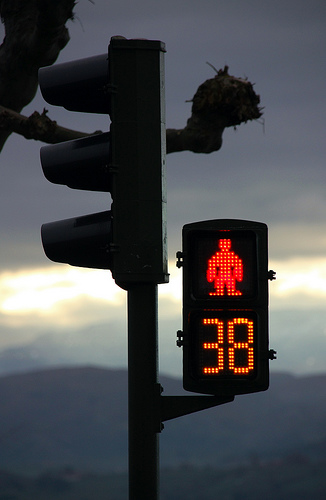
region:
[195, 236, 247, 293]
red man on light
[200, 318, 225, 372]
orange number on light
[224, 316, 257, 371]
orange number on light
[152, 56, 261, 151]
black protrusion behind light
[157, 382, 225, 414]
black protrusion on light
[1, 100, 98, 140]
black protrusion behind light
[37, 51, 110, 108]
black protrusion on light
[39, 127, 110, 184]
black protrusion on light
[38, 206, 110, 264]
black protrusion on light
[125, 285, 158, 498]
black pole of light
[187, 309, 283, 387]
light's in the shape of numbers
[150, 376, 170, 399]
bolt on a pole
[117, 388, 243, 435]
arm holding the lights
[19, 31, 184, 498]
pole with light's hanging on it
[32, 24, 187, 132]
top of the light pole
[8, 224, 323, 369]
horizon behind the light's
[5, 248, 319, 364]
cloud's in the sky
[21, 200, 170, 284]
bottom of the stop light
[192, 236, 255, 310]
light's shaped like a person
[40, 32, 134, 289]
light's on top of each other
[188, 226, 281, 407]
red signal light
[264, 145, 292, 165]
white clouds in blue sky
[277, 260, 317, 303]
white clouds in blue sky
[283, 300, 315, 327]
white clouds in blue sky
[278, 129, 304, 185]
white clouds in blue sky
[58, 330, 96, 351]
white clouds in blue sky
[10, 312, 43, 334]
white clouds in blue sky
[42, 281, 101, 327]
white clouds in blue sky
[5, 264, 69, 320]
white clouds in blue sky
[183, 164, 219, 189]
white clouds in blue sky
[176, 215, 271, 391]
number 38 and a symbol of a man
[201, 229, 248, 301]
red light symbol of a man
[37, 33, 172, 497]
side view of a traffic light pole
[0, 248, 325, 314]
sun shining through a cloudy sky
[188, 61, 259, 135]
a nest on a tree branch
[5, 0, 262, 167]
tree branch behind the traffic light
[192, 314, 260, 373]
the number 38 lit up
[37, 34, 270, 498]
traffic light post in focus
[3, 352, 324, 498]
out of focus blurry mountains in the distance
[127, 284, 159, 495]
pole holding up the traffic lights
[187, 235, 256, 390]
traffic light is on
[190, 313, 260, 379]
38 on the sign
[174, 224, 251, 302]
person on the sign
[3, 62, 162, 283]
side of traffic light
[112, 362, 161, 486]
pole for the lights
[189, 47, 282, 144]
side of the pole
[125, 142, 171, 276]
back of the light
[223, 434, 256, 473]
the background is blurry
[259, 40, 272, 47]
the sky is gray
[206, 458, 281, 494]
the mountains are hazy